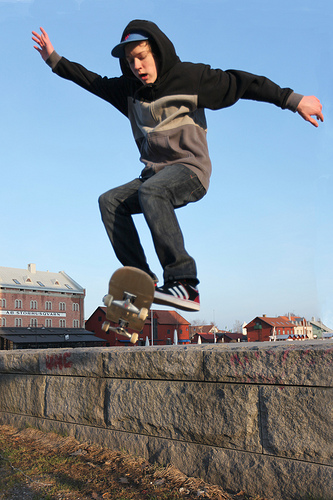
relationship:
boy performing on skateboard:
[28, 11, 326, 314] [99, 265, 156, 350]